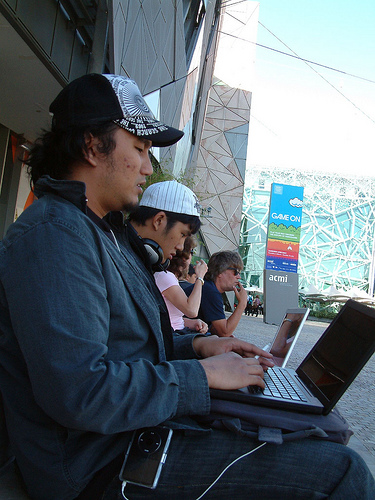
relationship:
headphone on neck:
[115, 214, 173, 262] [93, 213, 189, 300]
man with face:
[153, 249, 225, 316] [158, 209, 187, 246]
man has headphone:
[153, 249, 225, 316] [115, 214, 173, 262]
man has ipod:
[153, 249, 225, 316] [132, 396, 183, 466]